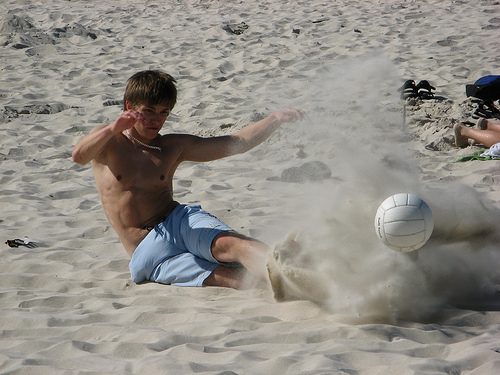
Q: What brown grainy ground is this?
A: Sand.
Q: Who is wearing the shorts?
A: A boy.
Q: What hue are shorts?
A: Brown.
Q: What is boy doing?
A: Diving.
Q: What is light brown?
A: Sand.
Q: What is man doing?
A: Kicking.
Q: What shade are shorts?
A: Light blue.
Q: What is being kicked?
A: Volley ball.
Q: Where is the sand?
A: On beach.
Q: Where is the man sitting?
A: Sand.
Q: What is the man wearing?
A: Trunks.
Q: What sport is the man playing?
A: Volleyball.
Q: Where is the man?
A: Beach.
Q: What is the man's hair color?
A: Brown.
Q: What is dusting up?
A: Sand.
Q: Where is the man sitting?
A: On the sand.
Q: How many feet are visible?
A: Two.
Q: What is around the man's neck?
A: A necklace.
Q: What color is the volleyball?
A: White.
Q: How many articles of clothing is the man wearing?
A: One.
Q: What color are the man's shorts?
A: Blue.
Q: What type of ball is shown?
A: Volleyball.